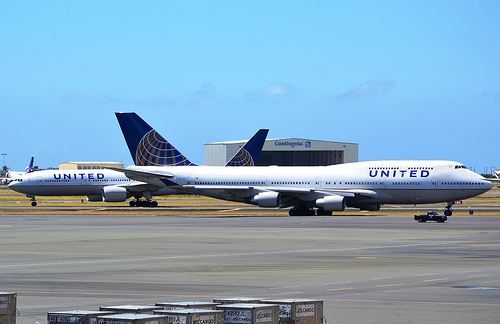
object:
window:
[393, 182, 395, 185]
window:
[409, 182, 411, 185]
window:
[359, 182, 360, 185]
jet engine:
[309, 192, 347, 211]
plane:
[124, 106, 478, 233]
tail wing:
[111, 109, 203, 166]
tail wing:
[221, 125, 270, 166]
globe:
[230, 148, 254, 168]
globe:
[134, 129, 198, 167]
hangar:
[198, 134, 361, 176]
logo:
[274, 140, 311, 148]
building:
[203, 138, 358, 168]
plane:
[114, 111, 494, 217]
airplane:
[105, 111, 494, 218]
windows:
[408, 167, 410, 169]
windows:
[475, 182, 477, 185]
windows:
[345, 182, 347, 185]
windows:
[369, 167, 371, 169]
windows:
[272, 182, 274, 184]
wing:
[262, 185, 357, 198]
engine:
[248, 191, 282, 207]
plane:
[99, 110, 494, 219]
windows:
[88, 180, 91, 182]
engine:
[305, 193, 345, 211]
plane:
[103, 111, 493, 216]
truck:
[414, 211, 448, 222]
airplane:
[8, 128, 275, 207]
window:
[469, 182, 472, 185]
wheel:
[444, 202, 452, 216]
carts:
[41, 297, 327, 321]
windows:
[195, 182, 197, 185]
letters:
[421, 170, 429, 178]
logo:
[369, 167, 430, 179]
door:
[431, 178, 439, 190]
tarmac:
[3, 212, 497, 317]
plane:
[7, 129, 271, 206]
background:
[9, 111, 497, 215]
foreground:
[4, 281, 498, 323]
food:
[72, 308, 279, 322]